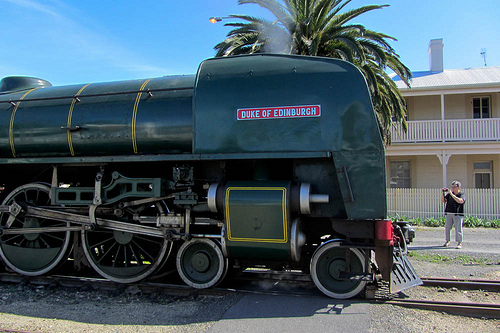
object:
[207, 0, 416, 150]
palm tree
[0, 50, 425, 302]
green train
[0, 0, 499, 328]
bad image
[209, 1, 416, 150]
tree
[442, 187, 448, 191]
camera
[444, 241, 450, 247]
white shoe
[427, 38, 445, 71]
chimney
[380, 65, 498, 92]
roof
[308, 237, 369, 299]
wheel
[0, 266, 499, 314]
rail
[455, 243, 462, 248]
shoe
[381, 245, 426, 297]
steam shovel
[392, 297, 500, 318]
steel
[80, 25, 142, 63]
clouds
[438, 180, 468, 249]
woman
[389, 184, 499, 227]
railings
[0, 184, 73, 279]
wheels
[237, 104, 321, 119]
sign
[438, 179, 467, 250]
person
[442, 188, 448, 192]
phone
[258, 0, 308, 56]
train steam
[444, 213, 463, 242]
khaki pants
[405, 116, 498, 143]
balcony railing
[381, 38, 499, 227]
beige house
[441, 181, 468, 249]
man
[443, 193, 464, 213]
shirt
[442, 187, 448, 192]
camera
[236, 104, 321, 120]
name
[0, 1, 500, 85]
sky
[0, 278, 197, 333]
gravel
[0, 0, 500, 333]
picture